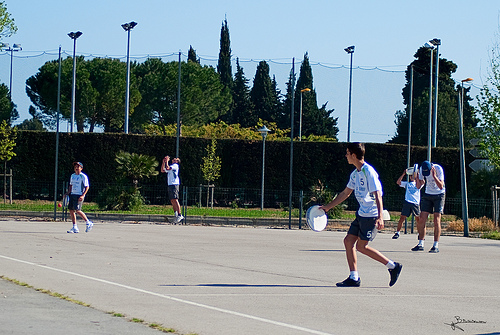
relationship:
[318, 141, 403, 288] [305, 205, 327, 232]
man has frisbee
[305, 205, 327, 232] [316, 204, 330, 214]
frisbee in hand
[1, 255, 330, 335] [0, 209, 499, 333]
line on playground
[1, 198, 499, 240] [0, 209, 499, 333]
grass near playground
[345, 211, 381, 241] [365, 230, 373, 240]
shorts have number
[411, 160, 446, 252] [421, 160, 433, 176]
man has cap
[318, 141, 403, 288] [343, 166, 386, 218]
man has shirt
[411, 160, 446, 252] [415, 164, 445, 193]
man has shirt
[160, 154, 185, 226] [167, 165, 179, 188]
man has shirt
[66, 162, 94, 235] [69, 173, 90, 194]
man has shirt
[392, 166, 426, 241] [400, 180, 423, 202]
man has shirt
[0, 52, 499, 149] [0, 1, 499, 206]
netting above trees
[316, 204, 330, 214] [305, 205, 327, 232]
hand holding frisbee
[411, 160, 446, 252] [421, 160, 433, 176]
man wearing cap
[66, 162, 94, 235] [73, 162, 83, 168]
man wearing cap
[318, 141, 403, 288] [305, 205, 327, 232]
man plays frisbee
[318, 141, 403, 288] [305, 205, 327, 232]
man throws frisbee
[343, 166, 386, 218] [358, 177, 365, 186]
shirt has number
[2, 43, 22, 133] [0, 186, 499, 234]
pole behind fence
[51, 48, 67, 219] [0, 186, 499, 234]
pole behind fence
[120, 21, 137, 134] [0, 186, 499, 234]
pole behind fence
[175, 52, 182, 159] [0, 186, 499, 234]
pole behind fence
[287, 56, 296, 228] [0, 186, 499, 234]
pole behind fence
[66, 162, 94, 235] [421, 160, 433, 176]
man has cap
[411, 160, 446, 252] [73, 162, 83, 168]
man has cap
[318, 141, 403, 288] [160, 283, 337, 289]
man cast shadow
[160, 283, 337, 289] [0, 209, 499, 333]
shadow on playground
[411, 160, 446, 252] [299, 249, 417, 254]
man cast shadow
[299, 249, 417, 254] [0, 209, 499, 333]
shadow on playground